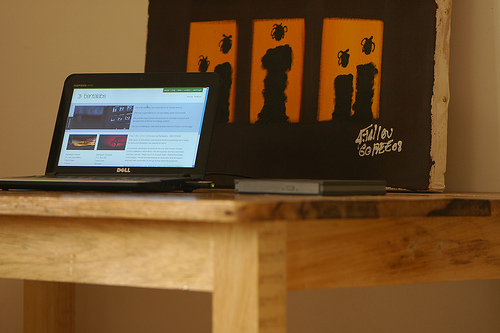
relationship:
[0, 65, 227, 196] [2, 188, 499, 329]
laptop on table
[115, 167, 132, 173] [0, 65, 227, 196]
dell on laptop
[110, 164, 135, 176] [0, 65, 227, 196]
brand name on laptop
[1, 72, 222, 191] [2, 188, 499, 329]
laptop on top of a table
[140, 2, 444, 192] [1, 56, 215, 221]
painting behind laptop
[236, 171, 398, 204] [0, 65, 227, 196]
external drive attached to laptop